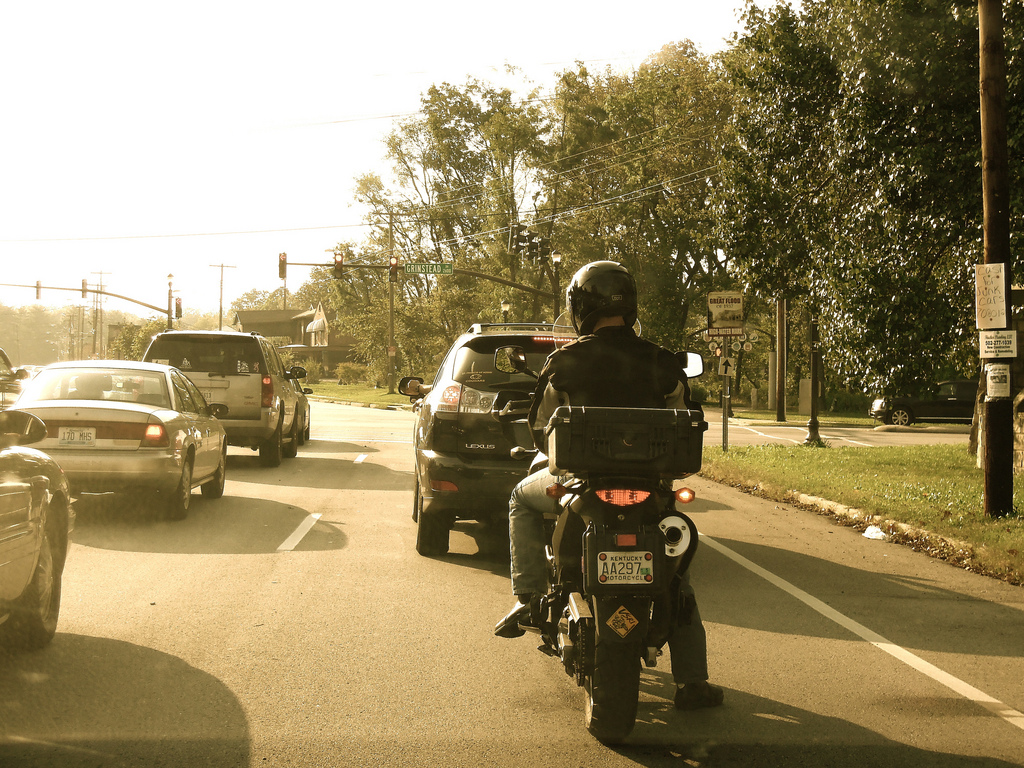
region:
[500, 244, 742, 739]
man riding black motorcycle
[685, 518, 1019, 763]
white solid line on the street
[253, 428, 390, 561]
white dash marks on the road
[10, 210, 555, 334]
traffic signals above the street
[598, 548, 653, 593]
license plate on the motorcycle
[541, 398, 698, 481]
black case on the motorcycle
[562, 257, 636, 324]
black helmet the rider is wearing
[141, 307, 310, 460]
suv stopped on the street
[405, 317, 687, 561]
black suv in front of the motorcycle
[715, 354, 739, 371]
black arrow on white sign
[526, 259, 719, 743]
a person on a motorcycle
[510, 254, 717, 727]
a person sitting on a motorcycle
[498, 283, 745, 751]
a person riding a motorcycle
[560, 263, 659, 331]
a person wearing a helmet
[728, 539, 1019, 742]
a white line painted on the edge of a street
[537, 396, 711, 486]
a black container on a motorcycle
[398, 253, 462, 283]
a green and white street sign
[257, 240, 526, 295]
three traffic lights on pole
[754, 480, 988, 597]
a concrete curb next to a street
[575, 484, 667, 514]
a red taillight on a motorcycle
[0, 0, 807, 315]
light of daytime sky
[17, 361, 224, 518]
car with glowing brake light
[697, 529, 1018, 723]
straight line on asphalt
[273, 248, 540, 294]
traffic lights on horizontal pole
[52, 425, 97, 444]
license plate of car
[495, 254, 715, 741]
rider sitting on motorbike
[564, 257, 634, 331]
helmet on rider's head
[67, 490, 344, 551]
shadow of car on asphalt